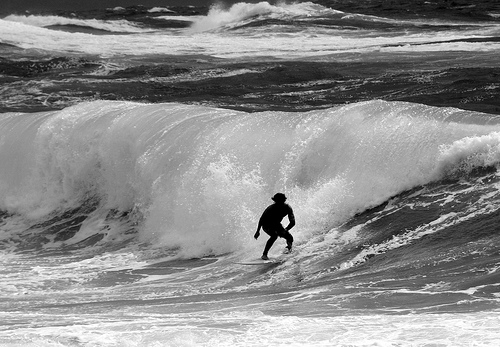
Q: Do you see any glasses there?
A: No, there are no glasses.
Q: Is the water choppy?
A: Yes, the water is choppy.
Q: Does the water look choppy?
A: Yes, the water is choppy.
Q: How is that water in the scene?
A: The water is choppy.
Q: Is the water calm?
A: No, the water is choppy.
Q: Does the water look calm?
A: No, the water is choppy.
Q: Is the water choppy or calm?
A: The water is choppy.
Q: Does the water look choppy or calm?
A: The water is choppy.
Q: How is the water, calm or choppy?
A: The water is choppy.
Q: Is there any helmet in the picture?
A: No, there are no helmets.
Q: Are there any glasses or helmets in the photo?
A: No, there are no helmets or glasses.